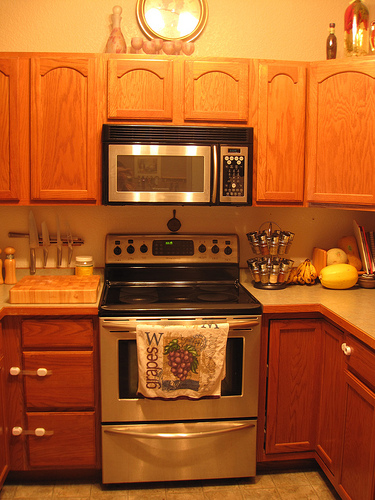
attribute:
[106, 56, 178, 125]
cabinet — wooden, small, wood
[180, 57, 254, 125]
cabinet — wooden, small, wood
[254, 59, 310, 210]
cabinet — wooden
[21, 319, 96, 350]
drawer — wooden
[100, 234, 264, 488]
stove — stainless steel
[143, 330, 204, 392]
design — grapes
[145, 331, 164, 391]
text — grapes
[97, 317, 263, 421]
door — silver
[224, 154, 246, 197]
display — buttons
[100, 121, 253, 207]
microwave — black, silver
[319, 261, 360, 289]
squash — yellow, large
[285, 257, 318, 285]
bananas — bunch, ripe, yellow, brown spotted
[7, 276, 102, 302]
chopping block — very large, thick, wooden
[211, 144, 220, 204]
handle — silver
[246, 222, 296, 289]
rack — spices